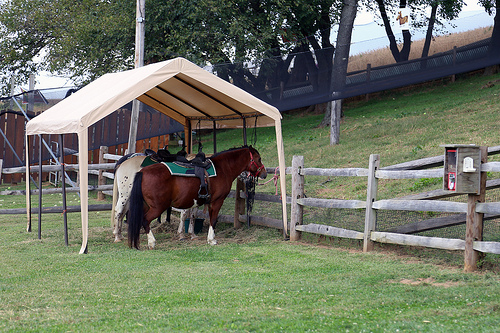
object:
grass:
[0, 246, 499, 332]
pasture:
[1, 0, 498, 331]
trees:
[412, 0, 458, 85]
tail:
[128, 171, 143, 250]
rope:
[247, 166, 280, 195]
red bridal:
[245, 148, 268, 180]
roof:
[20, 54, 283, 137]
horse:
[126, 144, 271, 252]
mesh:
[1, 0, 498, 169]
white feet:
[202, 231, 220, 245]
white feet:
[146, 240, 157, 248]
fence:
[0, 140, 500, 271]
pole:
[58, 137, 69, 244]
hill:
[325, 6, 500, 187]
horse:
[110, 148, 150, 244]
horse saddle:
[157, 142, 218, 206]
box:
[440, 142, 485, 195]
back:
[143, 149, 231, 183]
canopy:
[13, 46, 296, 246]